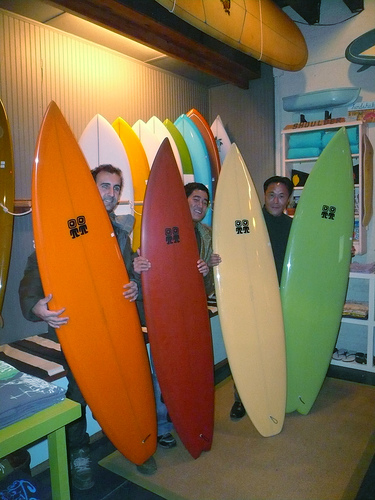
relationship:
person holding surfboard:
[19, 166, 157, 488] [31, 99, 158, 465]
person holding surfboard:
[133, 182, 214, 451] [139, 134, 216, 459]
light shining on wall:
[40, 8, 165, 96] [0, 10, 209, 343]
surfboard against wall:
[78, 113, 133, 242] [0, 10, 209, 343]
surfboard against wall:
[110, 115, 150, 249] [0, 10, 209, 343]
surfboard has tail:
[139, 134, 216, 459] [190, 435, 215, 461]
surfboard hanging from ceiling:
[152, 0, 310, 73] [269, 0, 373, 25]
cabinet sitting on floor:
[26, 312, 227, 465] [32, 356, 374, 499]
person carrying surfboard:
[19, 166, 157, 488] [31, 99, 158, 465]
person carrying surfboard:
[133, 182, 214, 451] [139, 134, 216, 459]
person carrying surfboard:
[209, 175, 356, 418] [209, 141, 287, 438]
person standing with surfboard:
[19, 166, 157, 488] [31, 99, 158, 465]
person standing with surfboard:
[133, 182, 214, 451] [139, 134, 216, 459]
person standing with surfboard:
[209, 175, 356, 418] [209, 141, 287, 438]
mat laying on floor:
[95, 375, 374, 498] [32, 356, 374, 499]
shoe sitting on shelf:
[343, 350, 356, 362] [330, 358, 366, 370]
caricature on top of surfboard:
[66, 218, 80, 239] [31, 99, 158, 465]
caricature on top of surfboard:
[76, 214, 88, 237] [31, 99, 158, 465]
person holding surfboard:
[209, 175, 356, 418] [209, 141, 287, 438]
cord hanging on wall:
[0, 204, 34, 219] [0, 10, 209, 343]